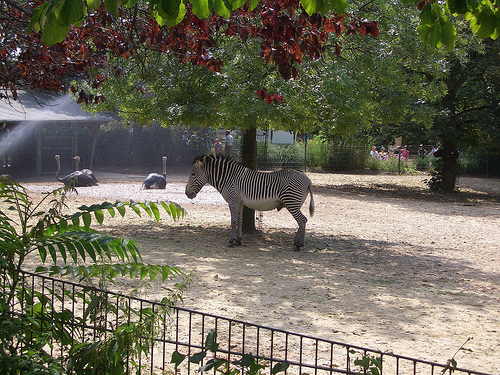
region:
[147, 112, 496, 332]
a zebra in a field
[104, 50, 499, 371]
a zebra in a dirt field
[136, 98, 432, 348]
a black and white zebra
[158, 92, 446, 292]
a zebra standing up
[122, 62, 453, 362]
a black and white standing up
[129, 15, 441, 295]
a tree with green leaves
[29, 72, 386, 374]
a zebra behind a fence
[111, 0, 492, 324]
a zebra standing in the shade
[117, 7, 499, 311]
a zebra standing under the tree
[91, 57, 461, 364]
a black and white zebra under the tree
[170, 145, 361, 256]
One zebra in a pen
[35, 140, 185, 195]
Birds on the sand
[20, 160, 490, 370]
The ground is sandy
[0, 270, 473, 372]
Metal fence surrounding the pen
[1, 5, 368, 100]
Red leaves hanging from the tree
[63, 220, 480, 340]
Shadow of the tree in the sand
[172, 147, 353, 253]
The zebra is facing left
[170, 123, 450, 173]
People behind a fence in the background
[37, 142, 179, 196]
Three ostriches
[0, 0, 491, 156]
The trees are lush with leaves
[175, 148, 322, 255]
A male zebra standing beneath a tree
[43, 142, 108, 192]
Two ostriches sitting together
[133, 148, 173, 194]
An ostrich sitting by itself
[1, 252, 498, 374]
The thin fence of a zoo enclosure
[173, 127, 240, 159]
A group of zoo visitors in mostly blue and grey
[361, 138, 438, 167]
A group of zoo visitors in mostly shades of pink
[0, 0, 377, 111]
Tree branches with dark red leaves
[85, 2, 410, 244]
A light green, thin-trunked tree with a zebra beneath it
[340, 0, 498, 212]
A shady dark green tree in the distance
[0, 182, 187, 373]
A bush with green leaves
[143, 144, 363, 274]
The zebra is black and white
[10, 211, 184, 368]
The leaves are green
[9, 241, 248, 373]
The fence is metal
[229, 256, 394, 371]
The ground is brown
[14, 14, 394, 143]
The leaves are brown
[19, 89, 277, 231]
A building is in the back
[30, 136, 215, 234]
Birds are in the back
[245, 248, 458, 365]
The ground has shadows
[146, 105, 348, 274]
The zebra is striped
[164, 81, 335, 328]
The trees are tall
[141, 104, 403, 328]
the zebra has stripes